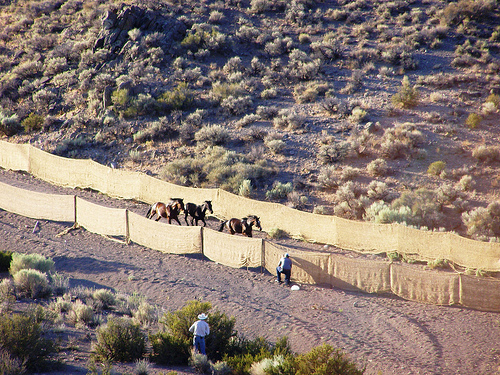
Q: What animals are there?
A: Horses.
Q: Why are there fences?
A: To control the horses.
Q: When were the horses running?
A: Daytime.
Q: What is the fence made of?
A: Fabric.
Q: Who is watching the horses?
A: Cowboys.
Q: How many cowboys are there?
A: Two.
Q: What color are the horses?
A: Brown.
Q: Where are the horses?
A: Inside the fence.